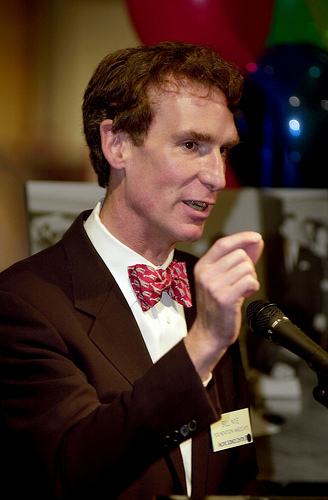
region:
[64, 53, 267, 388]
bill nye the science guy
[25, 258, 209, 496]
black suit on bill nye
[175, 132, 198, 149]
left eye of bill nye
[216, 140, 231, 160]
right eye of bill nye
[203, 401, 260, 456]
yellow name tag on shirt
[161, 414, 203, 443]
small buttons on suit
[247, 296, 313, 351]
black microphone on right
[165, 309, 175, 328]
small buttons on white shirt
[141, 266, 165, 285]
giraffe designs on bow tie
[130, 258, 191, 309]
a red bow tie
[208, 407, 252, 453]
a name tag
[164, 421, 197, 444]
black cuff buttons on the jacket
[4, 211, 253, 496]
a brown suit jacket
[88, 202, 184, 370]
a white collared shirt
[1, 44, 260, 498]
the man is speaking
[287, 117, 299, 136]
light reflection on the blue balloon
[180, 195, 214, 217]
his mouth is open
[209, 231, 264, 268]
his fingers are touching together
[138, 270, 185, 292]
A bow tie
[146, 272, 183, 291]
A red and white bow tie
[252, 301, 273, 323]
A black microphone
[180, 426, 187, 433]
A button on the jacket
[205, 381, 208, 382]
Shirt cuff seen under the jacket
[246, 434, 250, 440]
A black pin on the badge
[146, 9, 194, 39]
A red color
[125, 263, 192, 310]
Red and tan bow tie on man's neck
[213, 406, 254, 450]
Yellow tag on man's coat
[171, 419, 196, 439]
Buttons on coat cuff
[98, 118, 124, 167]
Right ear on man's head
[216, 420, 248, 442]
Words on yellow tag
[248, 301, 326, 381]
Microphone pointed at man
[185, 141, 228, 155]
Brown eyes in man's face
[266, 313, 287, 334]
Metal bands on microphone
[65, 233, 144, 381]
Lapel on man's brown jacket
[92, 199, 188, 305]
White shirt collar on man's shirt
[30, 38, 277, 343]
Bile Nye the science guy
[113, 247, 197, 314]
Red bow toe around neck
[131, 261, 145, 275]
Design on a red bow tie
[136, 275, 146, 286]
Design on a red bow tie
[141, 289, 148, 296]
Design on a red bow tie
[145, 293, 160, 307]
Design on a red bow tie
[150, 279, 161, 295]
Design on a red bow tie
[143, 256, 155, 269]
Design on a red bow tie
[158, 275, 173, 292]
Design on a red bow tie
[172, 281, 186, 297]
Design on a red bow tie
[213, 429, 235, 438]
A word on a tag.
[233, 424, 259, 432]
A word on a tag.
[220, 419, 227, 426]
A word on a tag.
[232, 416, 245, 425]
A word on a tag.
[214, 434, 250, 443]
A word on a tag.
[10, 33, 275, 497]
A person is standing up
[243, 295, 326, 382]
a black microphone device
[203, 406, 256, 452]
a rectangle name tag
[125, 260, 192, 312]
a red and grey bow tie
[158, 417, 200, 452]
buttons on the sleeve of a blazer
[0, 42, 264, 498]
a man wearing a bow tie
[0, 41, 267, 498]
a man wearing a white button down shirt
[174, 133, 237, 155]
eyes on a adult male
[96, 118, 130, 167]
ear on a adult male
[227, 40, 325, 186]
a blue helium balloon